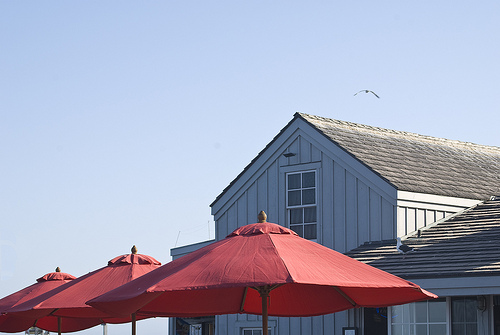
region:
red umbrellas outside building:
[17, 220, 348, 310]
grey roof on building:
[325, 67, 495, 192]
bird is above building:
[340, 81, 381, 103]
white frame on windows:
[270, 115, 341, 248]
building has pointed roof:
[227, 115, 481, 283]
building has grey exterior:
[223, 151, 382, 332]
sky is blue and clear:
[51, 25, 216, 190]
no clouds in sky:
[25, 43, 200, 185]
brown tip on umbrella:
[249, 195, 276, 229]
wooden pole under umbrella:
[242, 289, 277, 330]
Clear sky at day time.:
[0, 0, 498, 295]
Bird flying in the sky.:
[352, 85, 381, 103]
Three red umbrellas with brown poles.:
[1, 210, 439, 333]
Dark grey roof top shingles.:
[206, 108, 498, 278]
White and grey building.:
[167, 107, 497, 332]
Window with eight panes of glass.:
[282, 164, 322, 243]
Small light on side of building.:
[282, 151, 295, 158]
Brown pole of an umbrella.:
[255, 285, 277, 334]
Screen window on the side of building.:
[364, 305, 391, 334]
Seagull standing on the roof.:
[393, 236, 415, 261]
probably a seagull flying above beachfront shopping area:
[347, 82, 392, 106]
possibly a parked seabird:
[276, 142, 297, 160]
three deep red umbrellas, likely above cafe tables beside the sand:
[2, 204, 444, 334]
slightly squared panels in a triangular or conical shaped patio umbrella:
[85, 220, 445, 307]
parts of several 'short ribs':
[246, 280, 281, 291]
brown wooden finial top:
[245, 205, 275, 222]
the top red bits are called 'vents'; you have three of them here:
[20, 222, 300, 277]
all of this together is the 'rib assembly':
[241, 278, 286, 294]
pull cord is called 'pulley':
[265, 287, 275, 311]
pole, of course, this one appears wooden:
[250, 294, 280, 333]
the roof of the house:
[300, 111, 482, 186]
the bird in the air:
[354, 87, 382, 101]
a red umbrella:
[180, 229, 382, 311]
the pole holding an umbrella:
[258, 292, 272, 330]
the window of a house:
[286, 173, 315, 213]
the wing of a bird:
[371, 90, 381, 97]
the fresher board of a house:
[396, 189, 455, 211]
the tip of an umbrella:
[250, 210, 270, 225]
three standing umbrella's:
[17, 206, 389, 328]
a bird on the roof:
[393, 236, 418, 258]